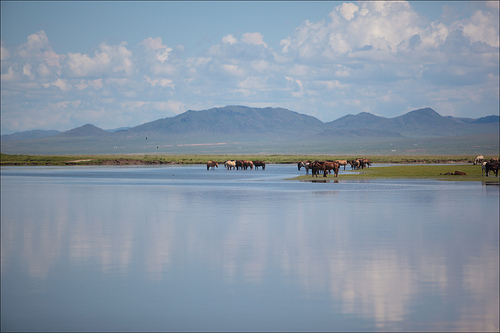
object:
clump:
[441, 171, 467, 177]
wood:
[438, 165, 468, 177]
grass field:
[299, 153, 499, 183]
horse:
[350, 159, 360, 170]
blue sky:
[4, 2, 259, 39]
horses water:
[198, 156, 376, 193]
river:
[0, 189, 499, 330]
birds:
[153, 141, 161, 147]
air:
[2, 3, 496, 150]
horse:
[335, 159, 353, 170]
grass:
[293, 163, 479, 181]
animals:
[204, 158, 268, 171]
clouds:
[2, 0, 497, 132]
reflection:
[1, 199, 498, 324]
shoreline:
[104, 156, 161, 165]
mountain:
[0, 104, 500, 142]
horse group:
[204, 158, 372, 183]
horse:
[482, 159, 500, 176]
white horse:
[470, 153, 488, 165]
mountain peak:
[408, 107, 443, 123]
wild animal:
[350, 157, 372, 170]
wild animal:
[335, 159, 350, 167]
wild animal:
[296, 159, 312, 174]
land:
[0, 105, 499, 182]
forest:
[1, 144, 476, 164]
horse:
[308, 158, 330, 177]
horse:
[323, 159, 339, 178]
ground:
[368, 162, 488, 182]